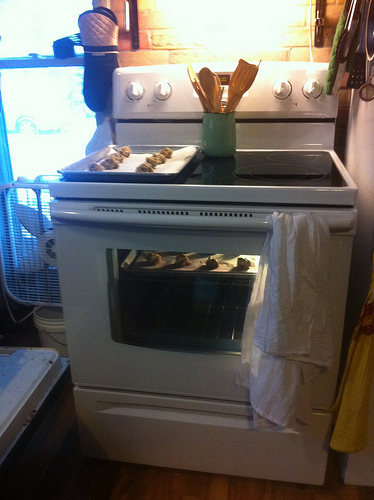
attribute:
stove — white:
[59, 65, 356, 488]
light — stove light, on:
[110, 245, 259, 286]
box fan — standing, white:
[0, 173, 66, 309]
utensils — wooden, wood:
[184, 58, 264, 116]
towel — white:
[231, 208, 337, 434]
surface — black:
[58, 149, 350, 189]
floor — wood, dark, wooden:
[2, 310, 373, 500]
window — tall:
[0, 1, 118, 283]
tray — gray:
[120, 247, 263, 280]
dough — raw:
[144, 249, 253, 272]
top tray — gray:
[54, 143, 205, 184]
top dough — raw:
[86, 144, 174, 176]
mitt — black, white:
[75, 6, 122, 115]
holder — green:
[199, 110, 237, 160]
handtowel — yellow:
[326, 274, 374, 456]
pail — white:
[30, 301, 71, 360]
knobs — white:
[124, 78, 325, 103]